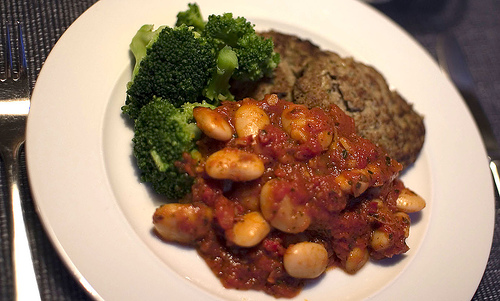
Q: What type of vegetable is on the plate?
A: Broccoli.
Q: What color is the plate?
A: White.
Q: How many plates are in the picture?
A: One.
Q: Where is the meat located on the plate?
A: Top right.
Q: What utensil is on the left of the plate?
A: Fork.